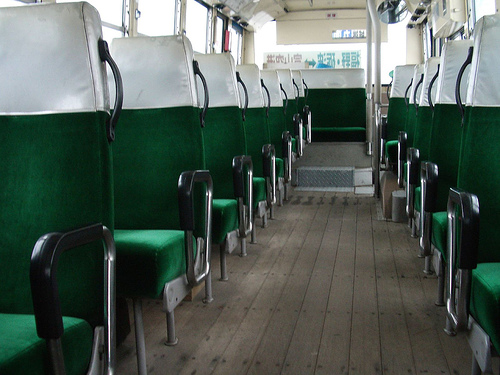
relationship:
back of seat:
[308, 65, 362, 125] [326, 97, 361, 123]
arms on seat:
[173, 171, 213, 268] [9, 15, 265, 246]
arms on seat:
[433, 187, 480, 332] [9, 15, 265, 246]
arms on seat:
[405, 157, 436, 249] [9, 15, 265, 246]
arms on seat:
[229, 145, 256, 238] [9, 15, 265, 246]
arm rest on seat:
[29, 215, 106, 336] [9, 15, 265, 246]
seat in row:
[460, 8, 484, 357] [367, 24, 484, 364]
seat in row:
[420, 32, 477, 294] [367, 24, 484, 364]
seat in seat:
[410, 58, 433, 239] [382, 59, 422, 220]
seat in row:
[382, 59, 422, 220] [367, 24, 484, 364]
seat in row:
[98, 36, 212, 346] [13, 0, 310, 354]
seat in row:
[193, 50, 251, 280] [13, 0, 310, 354]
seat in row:
[230, 56, 270, 236] [13, 0, 310, 354]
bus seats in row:
[381, 15, 499, 369] [391, 57, 484, 372]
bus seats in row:
[0, 1, 314, 372] [13, 0, 310, 354]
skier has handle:
[95, 37, 128, 138] [22, 220, 119, 371]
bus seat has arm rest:
[2, 7, 125, 367] [29, 215, 106, 336]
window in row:
[189, 6, 217, 53] [8, 1, 256, 57]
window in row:
[99, 2, 122, 37] [8, 1, 256, 57]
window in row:
[229, 27, 244, 62] [8, 1, 256, 57]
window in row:
[184, 5, 209, 47] [8, 1, 256, 57]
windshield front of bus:
[258, 19, 400, 74] [23, 7, 484, 356]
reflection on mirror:
[379, 0, 420, 21] [377, 2, 420, 28]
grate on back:
[301, 160, 361, 190] [294, 134, 382, 213]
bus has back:
[23, 7, 484, 356] [294, 134, 382, 213]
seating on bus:
[3, 2, 119, 374] [23, 7, 484, 356]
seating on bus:
[110, 31, 206, 323] [23, 7, 484, 356]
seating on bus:
[194, 47, 256, 275] [23, 7, 484, 356]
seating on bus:
[240, 61, 283, 234] [23, 7, 484, 356]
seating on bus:
[448, 14, 498, 371] [23, 7, 484, 356]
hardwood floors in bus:
[284, 214, 419, 367] [23, 7, 484, 356]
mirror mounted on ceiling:
[377, 2, 420, 28] [232, 1, 427, 66]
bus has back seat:
[23, 7, 484, 356] [296, 64, 378, 147]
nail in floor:
[344, 307, 352, 315] [98, 182, 477, 372]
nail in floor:
[300, 305, 310, 315] [98, 182, 477, 372]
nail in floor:
[396, 310, 404, 318] [98, 182, 477, 372]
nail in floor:
[407, 310, 415, 317] [98, 182, 477, 372]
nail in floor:
[375, 272, 382, 282] [98, 182, 477, 372]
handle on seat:
[89, 35, 134, 144] [95, 220, 194, 297]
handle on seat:
[185, 57, 216, 129] [0, 304, 100, 369]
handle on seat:
[232, 70, 254, 121] [204, 192, 240, 241]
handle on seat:
[450, 45, 480, 122] [204, 192, 240, 241]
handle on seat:
[424, 60, 442, 120] [464, 259, 499, 324]